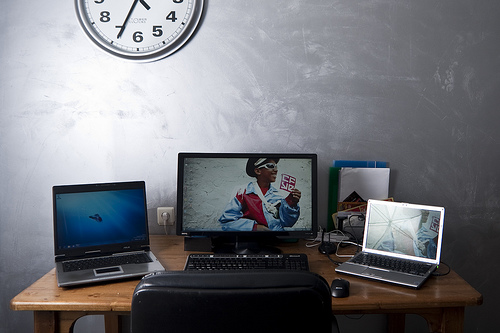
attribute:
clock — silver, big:
[74, 3, 211, 59]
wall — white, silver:
[1, 2, 500, 331]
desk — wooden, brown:
[13, 232, 483, 328]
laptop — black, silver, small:
[53, 186, 166, 291]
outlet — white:
[158, 207, 174, 223]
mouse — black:
[333, 277, 349, 295]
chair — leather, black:
[130, 272, 336, 332]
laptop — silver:
[336, 198, 446, 288]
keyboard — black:
[184, 255, 306, 272]